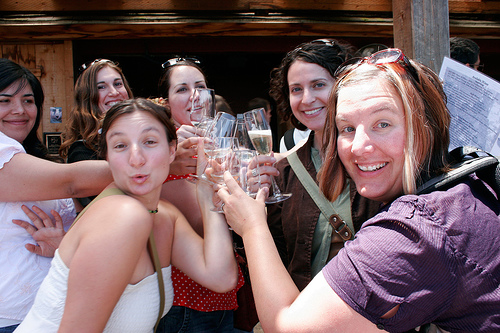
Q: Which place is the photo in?
A: It is at the restaurant.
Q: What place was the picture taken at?
A: It was taken at the restaurant.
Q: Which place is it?
A: It is a restaurant.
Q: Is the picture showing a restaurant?
A: Yes, it is showing a restaurant.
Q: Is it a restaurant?
A: Yes, it is a restaurant.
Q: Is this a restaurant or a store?
A: It is a restaurant.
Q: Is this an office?
A: No, it is a restaurant.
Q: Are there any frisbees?
A: No, there are no frisbees.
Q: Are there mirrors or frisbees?
A: No, there are no frisbees or mirrors.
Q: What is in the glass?
A: The champagne is in the glass.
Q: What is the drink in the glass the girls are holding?
A: The drink is champagne.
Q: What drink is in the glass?
A: The drink is champagne.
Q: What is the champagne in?
A: The champagne is in the glass.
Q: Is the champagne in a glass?
A: Yes, the champagne is in a glass.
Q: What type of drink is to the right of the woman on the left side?
A: The drink is champagne.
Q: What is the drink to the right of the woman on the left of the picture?
A: The drink is champagne.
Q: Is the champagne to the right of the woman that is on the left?
A: Yes, the champagne is to the right of the woman.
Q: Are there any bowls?
A: No, there are no bowls.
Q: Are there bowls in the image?
A: No, there are no bowls.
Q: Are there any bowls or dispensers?
A: No, there are no bowls or dispensers.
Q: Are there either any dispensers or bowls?
A: No, there are no bowls or dispensers.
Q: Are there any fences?
A: No, there are no fences.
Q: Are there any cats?
A: No, there are no cats.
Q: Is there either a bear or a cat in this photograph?
A: No, there are no cats or bears.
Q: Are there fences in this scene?
A: No, there are no fences.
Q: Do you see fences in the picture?
A: No, there are no fences.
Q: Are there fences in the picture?
A: No, there are no fences.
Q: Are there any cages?
A: No, there are no cages.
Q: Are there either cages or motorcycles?
A: No, there are no cages or motorcycles.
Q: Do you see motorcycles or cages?
A: No, there are no cages or motorcycles.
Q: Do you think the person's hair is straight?
A: No, the hair is curly.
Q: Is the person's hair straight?
A: No, the hair is curly.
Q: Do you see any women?
A: Yes, there is a woman.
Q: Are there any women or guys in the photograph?
A: Yes, there is a woman.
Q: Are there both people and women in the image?
A: Yes, there are both a woman and a person.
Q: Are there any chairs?
A: No, there are no chairs.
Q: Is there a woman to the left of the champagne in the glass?
A: Yes, there is a woman to the left of the champagne.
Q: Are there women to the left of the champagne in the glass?
A: Yes, there is a woman to the left of the champagne.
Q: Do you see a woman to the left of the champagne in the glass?
A: Yes, there is a woman to the left of the champagne.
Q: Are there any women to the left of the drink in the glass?
A: Yes, there is a woman to the left of the champagne.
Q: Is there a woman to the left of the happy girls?
A: Yes, there is a woman to the left of the girls.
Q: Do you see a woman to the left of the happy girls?
A: Yes, there is a woman to the left of the girls.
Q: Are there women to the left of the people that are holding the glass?
A: Yes, there is a woman to the left of the girls.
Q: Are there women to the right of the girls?
A: No, the woman is to the left of the girls.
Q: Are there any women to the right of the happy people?
A: No, the woman is to the left of the girls.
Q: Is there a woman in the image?
A: Yes, there is a woman.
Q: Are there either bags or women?
A: Yes, there is a woman.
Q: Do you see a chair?
A: No, there are no chairs.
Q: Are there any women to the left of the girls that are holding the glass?
A: Yes, there is a woman to the left of the girls.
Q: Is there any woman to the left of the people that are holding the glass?
A: Yes, there is a woman to the left of the girls.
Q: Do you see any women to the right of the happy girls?
A: No, the woman is to the left of the girls.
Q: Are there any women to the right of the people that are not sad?
A: No, the woman is to the left of the girls.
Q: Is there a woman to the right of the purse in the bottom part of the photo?
A: Yes, there is a woman to the right of the purse.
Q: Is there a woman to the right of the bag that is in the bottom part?
A: Yes, there is a woman to the right of the purse.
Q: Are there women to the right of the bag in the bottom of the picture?
A: Yes, there is a woman to the right of the purse.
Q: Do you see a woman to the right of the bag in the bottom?
A: Yes, there is a woman to the right of the purse.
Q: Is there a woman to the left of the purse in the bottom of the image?
A: No, the woman is to the right of the purse.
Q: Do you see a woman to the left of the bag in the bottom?
A: No, the woman is to the right of the purse.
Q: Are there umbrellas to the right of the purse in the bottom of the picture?
A: No, there is a woman to the right of the purse.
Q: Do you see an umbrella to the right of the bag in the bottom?
A: No, there is a woman to the right of the purse.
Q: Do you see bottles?
A: No, there are no bottles.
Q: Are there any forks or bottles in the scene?
A: No, there are no bottles or forks.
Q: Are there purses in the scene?
A: Yes, there is a purse.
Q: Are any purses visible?
A: Yes, there is a purse.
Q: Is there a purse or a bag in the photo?
A: Yes, there is a purse.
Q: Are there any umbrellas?
A: No, there are no umbrellas.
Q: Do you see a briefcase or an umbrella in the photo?
A: No, there are no umbrellas or briefcases.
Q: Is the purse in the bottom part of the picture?
A: Yes, the purse is in the bottom of the image.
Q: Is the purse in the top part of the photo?
A: No, the purse is in the bottom of the image.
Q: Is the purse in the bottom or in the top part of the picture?
A: The purse is in the bottom of the image.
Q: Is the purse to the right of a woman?
A: No, the purse is to the left of a woman.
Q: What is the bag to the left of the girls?
A: The bag is a purse.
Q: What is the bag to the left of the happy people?
A: The bag is a purse.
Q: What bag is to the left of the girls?
A: The bag is a purse.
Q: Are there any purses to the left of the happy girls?
A: Yes, there is a purse to the left of the girls.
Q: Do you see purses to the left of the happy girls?
A: Yes, there is a purse to the left of the girls.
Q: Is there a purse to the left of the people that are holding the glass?
A: Yes, there is a purse to the left of the girls.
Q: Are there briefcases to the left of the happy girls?
A: No, there is a purse to the left of the girls.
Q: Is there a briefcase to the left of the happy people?
A: No, there is a purse to the left of the girls.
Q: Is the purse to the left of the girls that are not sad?
A: Yes, the purse is to the left of the girls.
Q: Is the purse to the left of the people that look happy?
A: Yes, the purse is to the left of the girls.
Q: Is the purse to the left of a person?
A: Yes, the purse is to the left of a person.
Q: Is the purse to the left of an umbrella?
A: No, the purse is to the left of a person.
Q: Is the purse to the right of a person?
A: No, the purse is to the left of a person.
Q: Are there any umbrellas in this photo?
A: No, there are no umbrellas.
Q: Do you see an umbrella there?
A: No, there are no umbrellas.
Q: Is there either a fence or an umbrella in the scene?
A: No, there are no umbrellas or fences.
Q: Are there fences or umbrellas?
A: No, there are no umbrellas or fences.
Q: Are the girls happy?
A: Yes, the girls are happy.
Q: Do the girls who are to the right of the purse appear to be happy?
A: Yes, the girls are happy.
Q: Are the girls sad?
A: No, the girls are happy.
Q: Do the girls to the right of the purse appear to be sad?
A: No, the girls are happy.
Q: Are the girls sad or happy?
A: The girls are happy.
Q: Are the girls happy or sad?
A: The girls are happy.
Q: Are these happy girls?
A: Yes, these are happy girls.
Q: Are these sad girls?
A: No, these are happy girls.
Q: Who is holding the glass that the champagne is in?
A: The girls are holding the glass.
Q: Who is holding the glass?
A: The girls are holding the glass.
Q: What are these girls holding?
A: The girls are holding the glass.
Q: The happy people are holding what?
A: The girls are holding the glass.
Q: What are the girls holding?
A: The girls are holding the glass.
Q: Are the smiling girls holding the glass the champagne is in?
A: Yes, the girls are holding the glass.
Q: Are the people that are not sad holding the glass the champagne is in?
A: Yes, the girls are holding the glass.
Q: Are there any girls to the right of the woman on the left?
A: Yes, there are girls to the right of the woman.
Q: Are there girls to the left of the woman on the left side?
A: No, the girls are to the right of the woman.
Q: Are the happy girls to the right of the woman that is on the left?
A: Yes, the girls are to the right of the woman.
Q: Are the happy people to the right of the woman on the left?
A: Yes, the girls are to the right of the woman.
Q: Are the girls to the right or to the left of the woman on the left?
A: The girls are to the right of the woman.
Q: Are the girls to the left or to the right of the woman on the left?
A: The girls are to the right of the woman.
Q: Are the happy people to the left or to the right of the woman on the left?
A: The girls are to the right of the woman.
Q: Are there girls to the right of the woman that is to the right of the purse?
A: Yes, there are girls to the right of the woman.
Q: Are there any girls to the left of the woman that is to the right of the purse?
A: No, the girls are to the right of the woman.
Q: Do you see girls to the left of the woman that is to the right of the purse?
A: No, the girls are to the right of the woman.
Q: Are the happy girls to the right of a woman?
A: Yes, the girls are to the right of a woman.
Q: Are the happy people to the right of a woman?
A: Yes, the girls are to the right of a woman.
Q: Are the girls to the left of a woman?
A: No, the girls are to the right of a woman.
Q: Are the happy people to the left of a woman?
A: No, the girls are to the right of a woman.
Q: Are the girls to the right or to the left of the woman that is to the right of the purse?
A: The girls are to the right of the woman.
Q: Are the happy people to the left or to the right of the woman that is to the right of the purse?
A: The girls are to the right of the woman.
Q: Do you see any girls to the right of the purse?
A: Yes, there are girls to the right of the purse.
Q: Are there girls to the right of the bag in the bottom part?
A: Yes, there are girls to the right of the purse.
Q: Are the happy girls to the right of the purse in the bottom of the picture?
A: Yes, the girls are to the right of the purse.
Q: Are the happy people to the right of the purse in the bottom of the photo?
A: Yes, the girls are to the right of the purse.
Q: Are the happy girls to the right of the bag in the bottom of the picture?
A: Yes, the girls are to the right of the purse.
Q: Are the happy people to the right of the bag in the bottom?
A: Yes, the girls are to the right of the purse.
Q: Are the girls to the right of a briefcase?
A: No, the girls are to the right of the purse.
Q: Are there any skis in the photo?
A: No, there are no skis.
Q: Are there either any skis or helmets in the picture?
A: No, there are no skis or helmets.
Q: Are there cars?
A: No, there are no cars.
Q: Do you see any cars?
A: No, there are no cars.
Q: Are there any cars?
A: No, there are no cars.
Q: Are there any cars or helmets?
A: No, there are no cars or helmets.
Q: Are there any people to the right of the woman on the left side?
A: Yes, there is a person to the right of the woman.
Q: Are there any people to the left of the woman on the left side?
A: No, the person is to the right of the woman.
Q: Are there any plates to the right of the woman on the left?
A: No, there is a person to the right of the woman.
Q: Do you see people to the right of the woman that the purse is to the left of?
A: Yes, there is a person to the right of the woman.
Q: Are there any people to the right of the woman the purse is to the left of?
A: Yes, there is a person to the right of the woman.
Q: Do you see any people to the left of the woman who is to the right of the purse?
A: No, the person is to the right of the woman.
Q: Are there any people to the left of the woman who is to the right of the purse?
A: No, the person is to the right of the woman.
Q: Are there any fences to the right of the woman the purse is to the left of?
A: No, there is a person to the right of the woman.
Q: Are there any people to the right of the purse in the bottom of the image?
A: Yes, there is a person to the right of the purse.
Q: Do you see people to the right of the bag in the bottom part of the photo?
A: Yes, there is a person to the right of the purse.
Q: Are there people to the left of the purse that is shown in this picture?
A: No, the person is to the right of the purse.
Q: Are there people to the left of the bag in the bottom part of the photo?
A: No, the person is to the right of the purse.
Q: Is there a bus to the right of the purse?
A: No, there is a person to the right of the purse.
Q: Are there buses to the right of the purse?
A: No, there is a person to the right of the purse.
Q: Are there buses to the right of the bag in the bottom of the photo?
A: No, there is a person to the right of the purse.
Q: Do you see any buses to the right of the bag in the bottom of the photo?
A: No, there is a person to the right of the purse.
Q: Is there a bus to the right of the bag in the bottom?
A: No, there is a person to the right of the purse.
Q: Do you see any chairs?
A: No, there are no chairs.